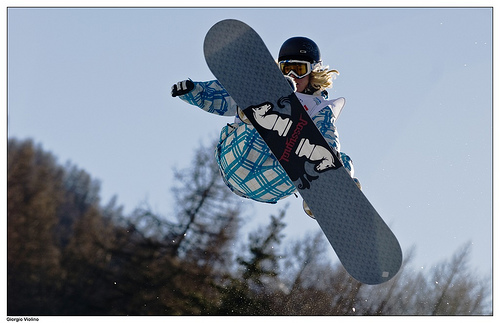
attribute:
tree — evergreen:
[10, 132, 494, 312]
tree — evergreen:
[372, 238, 418, 318]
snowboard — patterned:
[198, 15, 408, 293]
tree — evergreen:
[239, 197, 293, 286]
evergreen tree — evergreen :
[150, 170, 250, 287]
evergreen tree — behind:
[12, 138, 70, 293]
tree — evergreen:
[226, 203, 288, 317]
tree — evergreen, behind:
[24, 173, 134, 263]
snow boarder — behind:
[161, 9, 418, 283]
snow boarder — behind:
[178, 25, 401, 310]